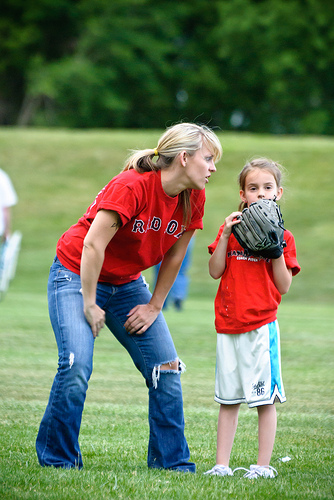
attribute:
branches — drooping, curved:
[26, 28, 316, 119]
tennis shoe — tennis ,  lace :
[241, 462, 276, 480]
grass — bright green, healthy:
[93, 415, 142, 477]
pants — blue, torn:
[60, 263, 179, 401]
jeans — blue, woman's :
[41, 259, 201, 473]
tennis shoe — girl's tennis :
[235, 464, 277, 478]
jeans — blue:
[32, 286, 183, 437]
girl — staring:
[205, 159, 320, 401]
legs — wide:
[29, 282, 253, 475]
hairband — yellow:
[152, 147, 158, 155]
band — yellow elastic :
[149, 144, 162, 161]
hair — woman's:
[122, 112, 226, 227]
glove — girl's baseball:
[235, 197, 286, 261]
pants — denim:
[38, 244, 211, 468]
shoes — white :
[200, 461, 281, 486]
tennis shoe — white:
[240, 457, 280, 486]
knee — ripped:
[138, 351, 185, 380]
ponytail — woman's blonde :
[119, 146, 158, 176]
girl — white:
[228, 155, 277, 475]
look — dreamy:
[249, 173, 275, 202]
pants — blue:
[46, 265, 183, 459]